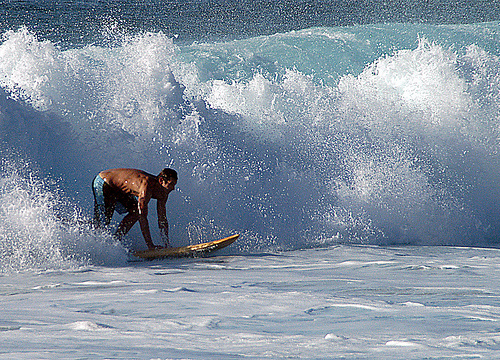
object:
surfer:
[91, 167, 177, 250]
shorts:
[91, 175, 139, 226]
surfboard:
[133, 233, 239, 259]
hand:
[165, 243, 173, 248]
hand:
[148, 243, 163, 249]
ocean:
[0, 13, 497, 272]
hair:
[158, 168, 179, 183]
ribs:
[119, 183, 138, 196]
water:
[0, 0, 497, 360]